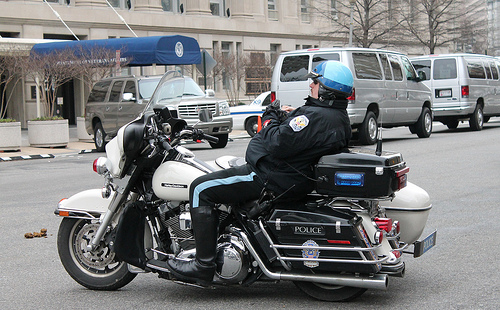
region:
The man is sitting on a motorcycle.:
[43, 40, 437, 304]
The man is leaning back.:
[56, 55, 439, 309]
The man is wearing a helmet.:
[44, 43, 450, 308]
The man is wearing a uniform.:
[49, 45, 454, 302]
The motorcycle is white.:
[46, 51, 444, 308]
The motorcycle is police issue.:
[48, 55, 448, 308]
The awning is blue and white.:
[21, 27, 216, 152]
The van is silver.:
[263, 35, 440, 152]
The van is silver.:
[403, 43, 498, 131]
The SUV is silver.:
[71, 65, 239, 158]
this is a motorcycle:
[100, 134, 315, 281]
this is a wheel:
[80, 233, 136, 304]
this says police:
[276, 201, 392, 250]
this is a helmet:
[262, 37, 415, 186]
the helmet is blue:
[281, 66, 381, 138]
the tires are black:
[38, 233, 125, 284]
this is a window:
[127, 93, 164, 116]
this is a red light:
[446, 83, 492, 111]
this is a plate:
[416, 71, 488, 132]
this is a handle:
[108, 118, 188, 160]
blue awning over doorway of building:
[16, 23, 206, 72]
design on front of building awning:
[163, 39, 190, 58]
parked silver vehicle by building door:
[65, 62, 243, 150]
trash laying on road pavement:
[8, 217, 60, 250]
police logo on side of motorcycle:
[296, 238, 331, 273]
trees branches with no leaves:
[318, 0, 489, 48]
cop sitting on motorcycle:
[59, 64, 466, 304]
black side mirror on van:
[412, 67, 432, 84]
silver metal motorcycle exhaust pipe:
[253, 267, 404, 297]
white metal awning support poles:
[35, 0, 151, 40]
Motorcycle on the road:
[55, 70, 438, 300]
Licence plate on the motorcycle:
[421, 232, 436, 253]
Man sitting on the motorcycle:
[163, 59, 353, 288]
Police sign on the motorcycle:
[292, 224, 324, 268]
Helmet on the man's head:
[306, 59, 354, 104]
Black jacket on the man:
[245, 96, 351, 189]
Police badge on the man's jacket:
[288, 114, 309, 132]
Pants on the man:
[187, 161, 264, 208]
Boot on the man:
[164, 206, 220, 288]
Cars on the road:
[83, 47, 498, 149]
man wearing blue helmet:
[284, 37, 370, 129]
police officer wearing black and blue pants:
[172, 156, 292, 213]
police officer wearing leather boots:
[156, 190, 248, 290]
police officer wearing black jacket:
[241, 85, 361, 179]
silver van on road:
[256, 26, 448, 150]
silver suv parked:
[53, 60, 255, 175]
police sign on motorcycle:
[277, 211, 340, 293]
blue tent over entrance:
[26, 27, 227, 99]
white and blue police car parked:
[206, 76, 293, 141]